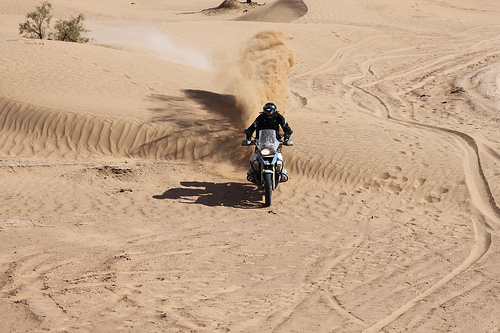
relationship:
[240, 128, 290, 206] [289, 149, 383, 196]
bike on sand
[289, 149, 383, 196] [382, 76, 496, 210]
sand has tire tracks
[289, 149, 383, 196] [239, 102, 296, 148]
sand behind biker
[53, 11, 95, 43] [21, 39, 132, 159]
trees behind sand dune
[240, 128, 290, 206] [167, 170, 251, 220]
bike casts shadow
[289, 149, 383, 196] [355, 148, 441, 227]
sand has foot prints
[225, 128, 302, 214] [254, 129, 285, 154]
bike has windshield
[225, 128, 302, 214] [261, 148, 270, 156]
bike has headlight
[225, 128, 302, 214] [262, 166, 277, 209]
bike has front tire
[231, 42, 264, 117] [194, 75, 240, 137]
sand casts shadow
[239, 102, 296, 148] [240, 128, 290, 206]
motorcyclist on bike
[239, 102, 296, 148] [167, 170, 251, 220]
motorcyclist casts shadow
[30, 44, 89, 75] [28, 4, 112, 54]
sand shows growing trees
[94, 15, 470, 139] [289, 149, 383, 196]
desert has sand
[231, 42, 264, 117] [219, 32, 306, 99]
sand in a cloud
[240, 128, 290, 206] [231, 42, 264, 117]
bike kicking up sand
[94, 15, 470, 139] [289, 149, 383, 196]
landscape has sand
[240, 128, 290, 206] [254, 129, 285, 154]
bike has windshield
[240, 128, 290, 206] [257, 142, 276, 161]
bike has headlight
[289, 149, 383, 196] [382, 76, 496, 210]
sand has wheel tracks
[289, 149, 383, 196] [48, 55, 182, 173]
sand forms dunes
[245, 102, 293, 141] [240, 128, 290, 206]
biker riding bike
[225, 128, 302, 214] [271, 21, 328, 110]
bike on dirt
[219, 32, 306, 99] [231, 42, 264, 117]
cloud made of sand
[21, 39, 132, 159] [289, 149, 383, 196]
dune made of sand